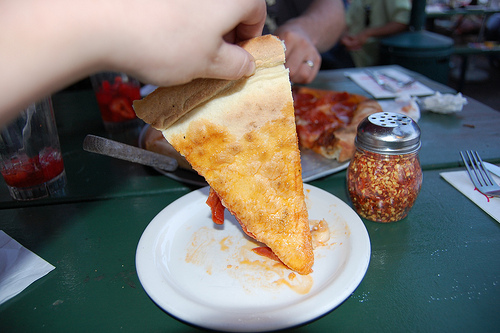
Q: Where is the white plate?
A: On the table.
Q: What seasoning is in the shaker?
A: Hot pepper flakes.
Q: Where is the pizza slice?
A: In the person's hand.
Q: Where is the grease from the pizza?
A: On the plate.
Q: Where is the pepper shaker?
A: Next to the white plate.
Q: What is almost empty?
A: Glass of beverage.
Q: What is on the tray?
A: Slices of pizza.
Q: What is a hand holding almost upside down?
A: A slice of pizza.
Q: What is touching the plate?
A: A slice of pizza.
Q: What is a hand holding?
A: A slice of pizza.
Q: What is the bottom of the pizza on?
A: A plate.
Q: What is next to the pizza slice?
A: Pepper shaker.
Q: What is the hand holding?
A: A cooked slice of pizza.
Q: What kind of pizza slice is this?
A: Baked.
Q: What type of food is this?
A: Pizza.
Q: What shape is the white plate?
A: Round.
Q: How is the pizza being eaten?
A: Person is using hands.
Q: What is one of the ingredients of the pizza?
A: Cheese.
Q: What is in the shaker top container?
A: Cracked pepper.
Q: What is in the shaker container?
A: Red pepper flakes.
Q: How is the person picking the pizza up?
A: With the left hand.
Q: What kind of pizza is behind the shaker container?
A: Pepperoni.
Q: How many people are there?
A: Two.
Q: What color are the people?
A: White.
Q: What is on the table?
A: Pepper flakes.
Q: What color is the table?
A: Green.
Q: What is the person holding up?
A: Pizza.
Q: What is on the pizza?
A: Grease.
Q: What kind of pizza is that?
A: Pepperoni.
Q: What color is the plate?
A: White.